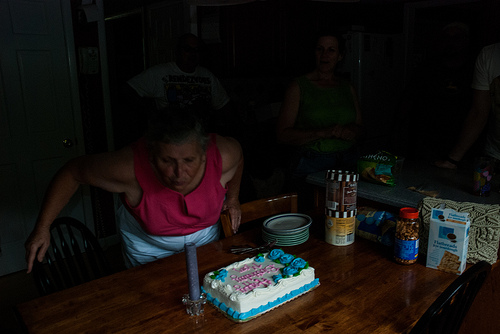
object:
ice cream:
[320, 163, 362, 249]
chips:
[352, 145, 419, 187]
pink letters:
[231, 258, 282, 292]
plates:
[250, 214, 317, 249]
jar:
[393, 197, 425, 274]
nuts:
[400, 222, 419, 241]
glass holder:
[182, 293, 209, 320]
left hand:
[218, 194, 243, 232]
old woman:
[19, 110, 258, 273]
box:
[421, 198, 477, 279]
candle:
[182, 243, 207, 315]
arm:
[216, 142, 242, 203]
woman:
[24, 112, 268, 264]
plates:
[246, 203, 327, 263]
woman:
[133, 122, 221, 210]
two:
[321, 170, 360, 247]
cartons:
[324, 167, 360, 247]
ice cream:
[323, 167, 358, 206]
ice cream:
[327, 207, 357, 251]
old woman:
[25, 119, 246, 272]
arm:
[39, 177, 75, 230]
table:
[1, 211, 486, 332]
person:
[98, 114, 283, 259]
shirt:
[112, 153, 232, 240]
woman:
[99, 130, 353, 317]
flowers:
[264, 245, 308, 275]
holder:
[180, 290, 210, 326]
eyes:
[151, 143, 208, 175]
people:
[19, 29, 494, 278]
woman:
[88, 124, 260, 244]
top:
[128, 166, 279, 243]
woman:
[104, 141, 285, 273]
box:
[426, 206, 471, 276]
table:
[13, 197, 498, 330]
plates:
[261, 210, 314, 249]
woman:
[26, 122, 244, 253]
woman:
[28, 115, 246, 271]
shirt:
[124, 139, 225, 236]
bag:
[360, 152, 398, 187]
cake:
[200, 248, 320, 320]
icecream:
[322, 159, 365, 252]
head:
[145, 107, 205, 194]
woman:
[15, 117, 253, 277]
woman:
[49, 82, 276, 286]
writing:
[227, 254, 286, 296]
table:
[13, 180, 469, 331]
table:
[0, 193, 460, 332]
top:
[289, 69, 369, 189]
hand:
[25, 234, 61, 274]